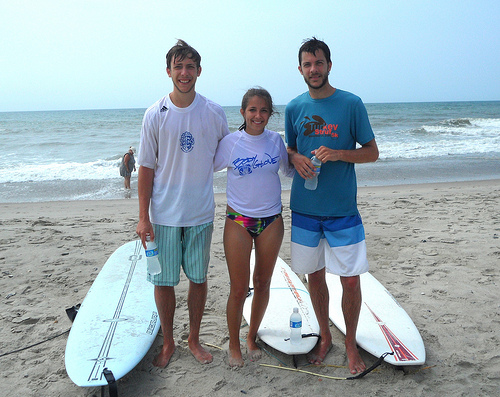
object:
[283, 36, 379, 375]
man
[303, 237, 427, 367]
surfboard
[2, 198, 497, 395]
sand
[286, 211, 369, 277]
sorts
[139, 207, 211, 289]
sorts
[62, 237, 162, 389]
board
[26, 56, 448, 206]
water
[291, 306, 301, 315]
cap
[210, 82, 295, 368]
woman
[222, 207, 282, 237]
bottom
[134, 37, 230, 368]
man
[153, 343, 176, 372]
feet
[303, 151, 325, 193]
bottle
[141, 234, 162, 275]
plastic bottle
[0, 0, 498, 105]
sky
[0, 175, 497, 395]
beach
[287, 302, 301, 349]
water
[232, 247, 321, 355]
surfboard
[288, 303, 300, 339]
bottle